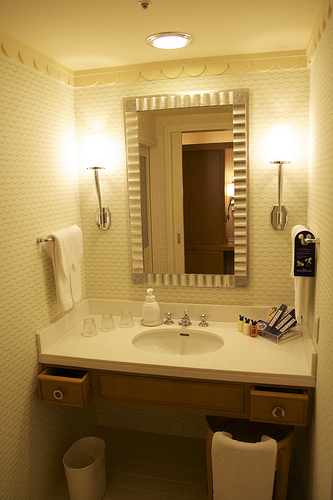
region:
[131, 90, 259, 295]
mirror on bath room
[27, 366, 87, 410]
open brown wooden drawer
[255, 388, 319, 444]
open brown wooden drawer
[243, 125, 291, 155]
white light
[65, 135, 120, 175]
white light in bathroom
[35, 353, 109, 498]
a dust bin under the partially opened draw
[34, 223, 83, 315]
a white towel is hanging on the bar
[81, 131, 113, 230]
the lamp mounted on the wall is glowing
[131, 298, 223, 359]
a wash basin sink with a tap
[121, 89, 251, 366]
a mirror is attached on the wall above wash basin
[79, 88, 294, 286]
electric lamps are mounted on both sides of the mirror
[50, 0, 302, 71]
an electric lamp in the ceiling is turned on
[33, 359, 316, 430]
two wooden drawers are partially opened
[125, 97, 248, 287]
the reflection in the mirror is shown a glowing electric lamp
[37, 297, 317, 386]
sink in middle of bathroom vanity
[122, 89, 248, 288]
rectangle mirror in decorative frame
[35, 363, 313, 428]
two open wood drawers with round handles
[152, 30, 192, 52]
bright white ceiling light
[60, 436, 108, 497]
white plastic trash can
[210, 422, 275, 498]
white bath towel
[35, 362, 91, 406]
small brown wooden drawer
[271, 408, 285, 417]
metal handle on a drawer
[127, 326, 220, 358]
white porcelain sink basin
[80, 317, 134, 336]
upside down plastic cups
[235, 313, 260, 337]
three small lotion bottles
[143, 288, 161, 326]
a large soap dispenser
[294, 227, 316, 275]
a micky mouse door hanger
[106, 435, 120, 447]
a tile in a floor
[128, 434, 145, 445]
a tile in a floor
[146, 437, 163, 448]
a tile in a floor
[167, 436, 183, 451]
a tile in a floor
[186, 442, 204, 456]
a tile in a floor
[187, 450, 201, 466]
a tile in a floor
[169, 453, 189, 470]
a tile in a floor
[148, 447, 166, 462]
a tile in a floor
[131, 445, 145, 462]
a tile in a floor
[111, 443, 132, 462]
a tile in a floor